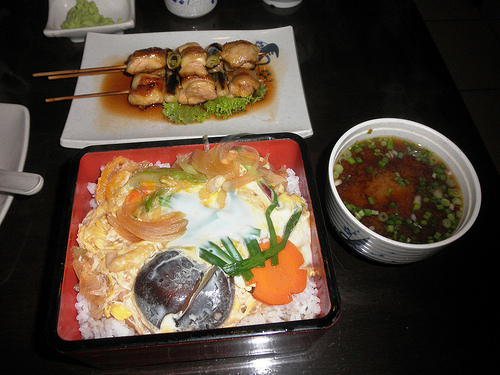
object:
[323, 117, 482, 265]
bowl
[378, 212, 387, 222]
onion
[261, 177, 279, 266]
bean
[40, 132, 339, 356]
dish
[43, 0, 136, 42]
dish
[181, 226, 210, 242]
liquid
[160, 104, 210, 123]
garnish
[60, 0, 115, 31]
wasabi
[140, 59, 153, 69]
meat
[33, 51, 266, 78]
stick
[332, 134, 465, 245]
miso soup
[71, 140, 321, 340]
food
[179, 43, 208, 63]
fish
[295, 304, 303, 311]
rice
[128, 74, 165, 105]
food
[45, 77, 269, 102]
skewer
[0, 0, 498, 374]
table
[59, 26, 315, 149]
plate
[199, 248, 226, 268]
bean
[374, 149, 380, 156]
onion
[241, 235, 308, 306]
circle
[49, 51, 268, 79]
skewering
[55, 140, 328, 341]
lining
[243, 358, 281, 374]
light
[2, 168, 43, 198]
utensil